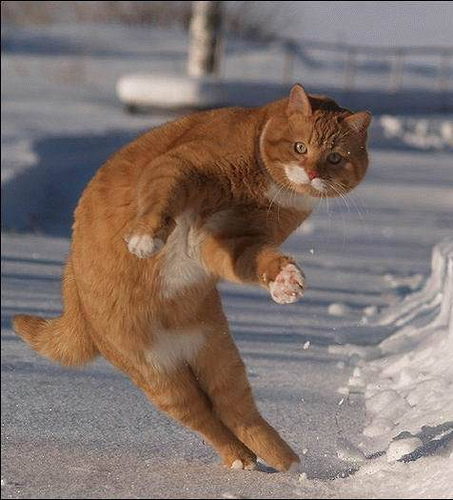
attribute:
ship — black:
[123, 0, 266, 116]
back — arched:
[61, 38, 306, 254]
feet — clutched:
[184, 397, 384, 493]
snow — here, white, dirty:
[331, 118, 448, 378]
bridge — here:
[291, 24, 445, 129]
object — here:
[123, 72, 277, 126]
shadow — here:
[20, 86, 159, 220]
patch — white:
[169, 218, 231, 295]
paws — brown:
[254, 249, 326, 299]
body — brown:
[75, 134, 228, 363]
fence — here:
[269, 28, 409, 80]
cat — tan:
[14, 78, 375, 476]